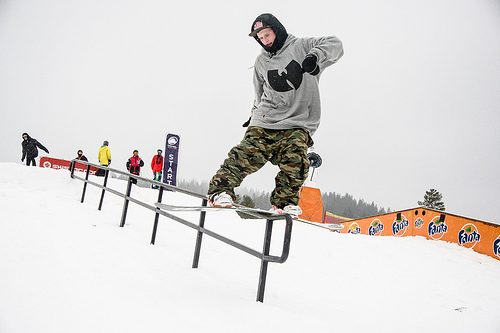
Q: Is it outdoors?
A: Yes, it is outdoors.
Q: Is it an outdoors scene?
A: Yes, it is outdoors.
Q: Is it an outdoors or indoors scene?
A: It is outdoors.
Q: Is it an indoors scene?
A: No, it is outdoors.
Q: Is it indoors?
A: No, it is outdoors.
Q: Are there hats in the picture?
A: Yes, there is a hat.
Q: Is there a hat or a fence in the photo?
A: Yes, there is a hat.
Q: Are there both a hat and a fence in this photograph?
A: Yes, there are both a hat and a fence.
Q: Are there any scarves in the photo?
A: No, there are no scarves.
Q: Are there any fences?
A: Yes, there is a fence.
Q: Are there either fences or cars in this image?
A: Yes, there is a fence.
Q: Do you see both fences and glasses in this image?
A: No, there is a fence but no glasses.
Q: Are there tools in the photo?
A: No, there are no tools.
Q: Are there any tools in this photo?
A: No, there are no tools.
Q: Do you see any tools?
A: No, there are no tools.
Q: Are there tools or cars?
A: No, there are no tools or cars.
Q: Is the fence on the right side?
A: Yes, the fence is on the right of the image.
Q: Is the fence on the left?
A: No, the fence is on the right of the image.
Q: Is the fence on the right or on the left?
A: The fence is on the right of the image.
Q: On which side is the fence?
A: The fence is on the right of the image.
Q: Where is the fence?
A: The fence is on the hill.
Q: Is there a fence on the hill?
A: Yes, there is a fence on the hill.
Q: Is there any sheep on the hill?
A: No, there is a fence on the hill.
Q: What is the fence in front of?
A: The fence is in front of the tree.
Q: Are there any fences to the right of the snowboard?
A: Yes, there is a fence to the right of the snowboard.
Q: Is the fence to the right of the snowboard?
A: Yes, the fence is to the right of the snowboard.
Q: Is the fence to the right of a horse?
A: No, the fence is to the right of the snowboard.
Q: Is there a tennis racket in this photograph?
A: No, there are no rackets.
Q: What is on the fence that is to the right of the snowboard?
A: The logo is on the fence.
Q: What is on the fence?
A: The logo is on the fence.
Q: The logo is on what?
A: The logo is on the fence.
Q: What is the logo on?
A: The logo is on the fence.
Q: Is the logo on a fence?
A: Yes, the logo is on a fence.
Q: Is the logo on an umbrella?
A: No, the logo is on a fence.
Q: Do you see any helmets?
A: No, there are no helmets.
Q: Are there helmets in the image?
A: No, there are no helmets.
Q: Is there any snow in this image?
A: Yes, there is snow.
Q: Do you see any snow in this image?
A: Yes, there is snow.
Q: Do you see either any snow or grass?
A: Yes, there is snow.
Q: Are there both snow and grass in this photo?
A: No, there is snow but no grass.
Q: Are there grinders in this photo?
A: No, there are no grinders.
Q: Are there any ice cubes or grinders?
A: No, there are no grinders or ice cubes.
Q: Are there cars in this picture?
A: No, there are no cars.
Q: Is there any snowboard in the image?
A: Yes, there is a snowboard.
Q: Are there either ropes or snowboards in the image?
A: Yes, there is a snowboard.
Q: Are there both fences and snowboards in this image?
A: Yes, there are both a snowboard and a fence.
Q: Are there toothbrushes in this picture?
A: No, there are no toothbrushes.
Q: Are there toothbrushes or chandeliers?
A: No, there are no toothbrushes or chandeliers.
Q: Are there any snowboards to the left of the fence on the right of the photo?
A: Yes, there is a snowboard to the left of the fence.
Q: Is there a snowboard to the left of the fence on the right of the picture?
A: Yes, there is a snowboard to the left of the fence.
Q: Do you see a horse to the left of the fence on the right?
A: No, there is a snowboard to the left of the fence.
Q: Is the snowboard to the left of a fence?
A: Yes, the snowboard is to the left of a fence.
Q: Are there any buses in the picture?
A: No, there are no buses.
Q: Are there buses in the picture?
A: No, there are no buses.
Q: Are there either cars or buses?
A: No, there are no buses or cars.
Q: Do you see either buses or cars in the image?
A: No, there are no buses or cars.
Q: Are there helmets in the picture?
A: No, there are no helmets.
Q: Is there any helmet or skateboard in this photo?
A: No, there are no helmets or skateboards.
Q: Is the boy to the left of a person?
A: No, the boy is to the right of a person.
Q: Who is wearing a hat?
A: The boy is wearing a hat.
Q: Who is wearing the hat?
A: The boy is wearing a hat.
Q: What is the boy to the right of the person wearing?
A: The boy is wearing a hat.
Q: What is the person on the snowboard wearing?
A: The boy is wearing a hat.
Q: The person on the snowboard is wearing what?
A: The boy is wearing a hat.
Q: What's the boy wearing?
A: The boy is wearing a hat.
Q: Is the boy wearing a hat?
A: Yes, the boy is wearing a hat.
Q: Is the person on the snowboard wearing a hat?
A: Yes, the boy is wearing a hat.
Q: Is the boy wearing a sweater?
A: No, the boy is wearing a hat.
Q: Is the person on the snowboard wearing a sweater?
A: No, the boy is wearing a hat.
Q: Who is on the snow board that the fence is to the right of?
A: The boy is on the snowboard.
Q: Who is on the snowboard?
A: The boy is on the snowboard.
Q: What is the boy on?
A: The boy is on the snow board.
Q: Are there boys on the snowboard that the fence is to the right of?
A: Yes, there is a boy on the snow board.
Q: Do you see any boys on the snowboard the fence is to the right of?
A: Yes, there is a boy on the snow board.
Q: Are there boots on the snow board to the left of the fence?
A: No, there is a boy on the snow board.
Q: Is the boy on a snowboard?
A: Yes, the boy is on a snowboard.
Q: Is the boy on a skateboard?
A: No, the boy is on a snowboard.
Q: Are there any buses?
A: No, there are no buses.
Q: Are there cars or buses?
A: No, there are no buses or cars.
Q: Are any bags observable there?
A: No, there are no bags.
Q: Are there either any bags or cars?
A: No, there are no bags or cars.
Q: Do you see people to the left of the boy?
A: Yes, there is a person to the left of the boy.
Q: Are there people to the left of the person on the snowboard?
A: Yes, there is a person to the left of the boy.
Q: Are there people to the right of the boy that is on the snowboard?
A: No, the person is to the left of the boy.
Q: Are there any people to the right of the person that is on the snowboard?
A: No, the person is to the left of the boy.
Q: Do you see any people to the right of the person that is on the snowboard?
A: No, the person is to the left of the boy.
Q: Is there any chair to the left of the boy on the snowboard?
A: No, there is a person to the left of the boy.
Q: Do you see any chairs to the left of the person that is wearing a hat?
A: No, there is a person to the left of the boy.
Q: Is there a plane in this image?
A: No, there are no airplanes.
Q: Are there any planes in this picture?
A: No, there are no planes.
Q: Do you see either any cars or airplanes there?
A: No, there are no airplanes or cars.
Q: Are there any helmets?
A: No, there are no helmets.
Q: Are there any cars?
A: No, there are no cars.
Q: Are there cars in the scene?
A: No, there are no cars.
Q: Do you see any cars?
A: No, there are no cars.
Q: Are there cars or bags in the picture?
A: No, there are no cars or bags.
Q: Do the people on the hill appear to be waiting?
A: Yes, the people are waiting.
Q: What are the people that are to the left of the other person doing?
A: The people are waiting.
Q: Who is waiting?
A: The people are waiting.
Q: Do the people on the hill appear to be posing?
A: No, the people are waiting.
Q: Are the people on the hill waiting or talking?
A: The people are waiting.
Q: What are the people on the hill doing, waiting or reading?
A: The people are waiting.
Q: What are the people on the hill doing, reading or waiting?
A: The people are waiting.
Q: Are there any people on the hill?
A: Yes, there are people on the hill.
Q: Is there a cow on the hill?
A: No, there are people on the hill.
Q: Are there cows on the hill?
A: No, there are people on the hill.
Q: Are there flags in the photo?
A: No, there are no flags.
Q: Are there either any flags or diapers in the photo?
A: No, there are no flags or diapers.